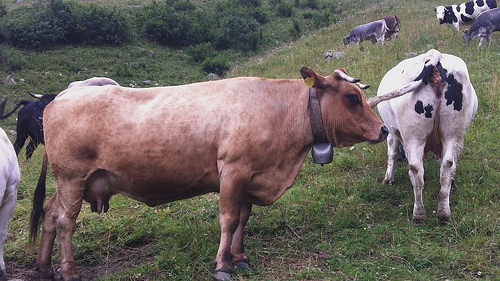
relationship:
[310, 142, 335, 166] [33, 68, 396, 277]
bell on cow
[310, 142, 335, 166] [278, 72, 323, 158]
bell on neck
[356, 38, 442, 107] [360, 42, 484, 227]
tail on cow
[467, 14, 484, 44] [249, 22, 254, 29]
cow on hill side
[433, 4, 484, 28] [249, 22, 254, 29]
cow on hill side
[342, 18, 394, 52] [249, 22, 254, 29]
cow on hill side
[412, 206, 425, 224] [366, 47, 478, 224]
hoof on cow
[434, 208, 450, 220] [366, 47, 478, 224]
hoof on cow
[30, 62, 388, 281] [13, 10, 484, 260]
brown cow in field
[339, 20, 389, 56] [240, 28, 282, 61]
cow in field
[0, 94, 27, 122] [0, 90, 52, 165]
tail on cow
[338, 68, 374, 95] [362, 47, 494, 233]
horn on cow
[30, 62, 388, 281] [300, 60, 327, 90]
brown cow in ear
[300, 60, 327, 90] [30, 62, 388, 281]
ear on brown cow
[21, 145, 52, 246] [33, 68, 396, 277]
tail tip on cow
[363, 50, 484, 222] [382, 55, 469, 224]
backside on cow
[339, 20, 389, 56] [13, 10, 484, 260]
cow grazing in field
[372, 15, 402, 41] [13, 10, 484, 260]
cow grazing in field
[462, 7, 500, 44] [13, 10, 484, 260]
cow grazing in field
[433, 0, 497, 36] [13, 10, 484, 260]
cow grazing in field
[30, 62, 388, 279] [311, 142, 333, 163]
brown cow wearing bell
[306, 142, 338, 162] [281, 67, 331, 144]
bell around neck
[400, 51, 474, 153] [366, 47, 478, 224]
behind on cow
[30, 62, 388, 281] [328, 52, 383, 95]
brown cow with horns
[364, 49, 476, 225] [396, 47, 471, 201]
rear on cow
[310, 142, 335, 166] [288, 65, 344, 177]
bell on neck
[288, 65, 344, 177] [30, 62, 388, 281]
neck on brown cow